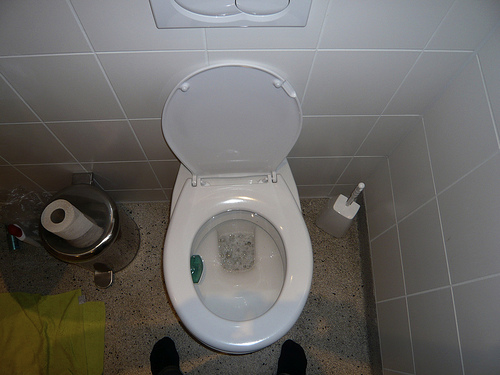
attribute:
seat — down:
[149, 168, 326, 361]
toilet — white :
[106, 55, 358, 360]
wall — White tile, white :
[355, 17, 498, 373]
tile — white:
[368, 221, 405, 301]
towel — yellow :
[11, 307, 101, 367]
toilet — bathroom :
[127, 56, 311, 358]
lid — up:
[137, 57, 319, 178]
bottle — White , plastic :
[5, 222, 42, 247]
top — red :
[6, 222, 21, 238]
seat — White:
[165, 173, 315, 356]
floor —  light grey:
[314, 248, 365, 368]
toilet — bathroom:
[138, 54, 323, 355]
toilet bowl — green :
[162, 84, 312, 345]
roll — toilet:
[33, 201, 112, 255]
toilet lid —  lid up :
[160, 62, 305, 176]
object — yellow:
[6, 282, 96, 371]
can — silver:
[28, 177, 143, 292]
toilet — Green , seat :
[158, 59, 315, 356]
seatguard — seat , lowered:
[160, 172, 317, 353]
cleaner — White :
[316, 177, 371, 241]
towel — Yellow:
[16, 290, 103, 371]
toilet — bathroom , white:
[153, 70, 323, 366]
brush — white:
[315, 180, 366, 237]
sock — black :
[148, 332, 180, 373]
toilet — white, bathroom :
[157, 169, 334, 353]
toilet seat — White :
[162, 175, 314, 356]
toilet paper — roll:
[40, 197, 94, 239]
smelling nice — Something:
[129, 241, 263, 298]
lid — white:
[117, 46, 299, 205]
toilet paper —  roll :
[40, 196, 102, 245]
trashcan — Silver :
[29, 173, 146, 279]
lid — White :
[158, 61, 305, 184]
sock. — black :
[149, 330, 312, 372]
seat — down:
[161, 176, 317, 340]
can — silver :
[35, 193, 139, 285]